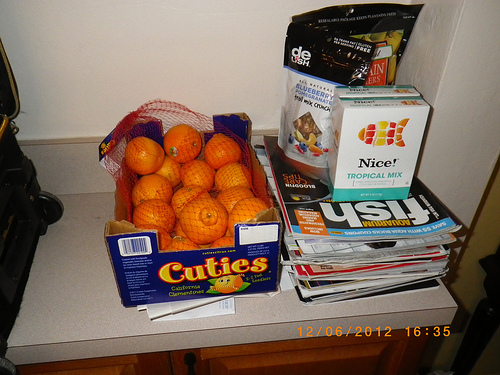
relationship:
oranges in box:
[124, 135, 233, 223] [101, 214, 289, 309]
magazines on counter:
[291, 191, 437, 313] [31, 203, 427, 336]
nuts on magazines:
[284, 28, 435, 212] [291, 191, 437, 313]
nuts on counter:
[284, 28, 435, 212] [31, 203, 427, 336]